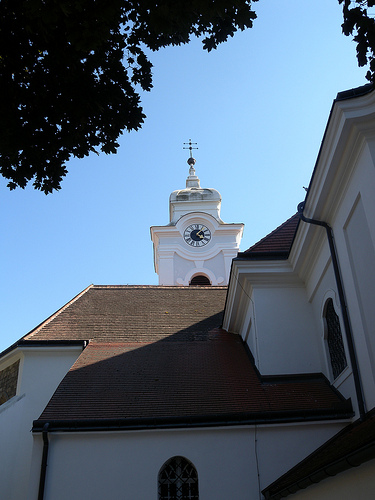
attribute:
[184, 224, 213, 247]
clock — part of tower, on a tower, black, white, showing time, on tower, on steeple, large, at top, on building, circular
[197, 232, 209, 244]
clock hands — gold, on a clock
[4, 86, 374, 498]
building — in shadow, white, large, church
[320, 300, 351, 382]
window — one of 3 seen, interesting shape, shaped, on building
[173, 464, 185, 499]
grating — over all windows, metal, made of iron bars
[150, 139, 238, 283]
steeple — black, white, tall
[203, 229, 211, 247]
numbers — roman numerals, black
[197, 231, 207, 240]
clock hands — showing 4:07, gold, gold colored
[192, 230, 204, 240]
center — black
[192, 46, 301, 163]
sky — blue, clear, sunny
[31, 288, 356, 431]
roof — brown, shingled, on the building, one of a few, reddish brown, on white building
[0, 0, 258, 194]
tree — near to church, large, above building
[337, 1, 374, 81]
branch — green, deciduous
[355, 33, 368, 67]
leaves — green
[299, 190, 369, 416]
drain pipe — for water, black, for storms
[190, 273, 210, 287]
church window — rounded at top, on tower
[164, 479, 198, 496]
bars — dark, in window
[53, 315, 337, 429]
shadow — from sun, on church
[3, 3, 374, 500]
scene — inclusive of sky, inclusive of tree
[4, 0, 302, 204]
sky and tree — in scene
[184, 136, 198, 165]
weather vane — atop tower, on tower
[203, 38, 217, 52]
leaf — on a tree